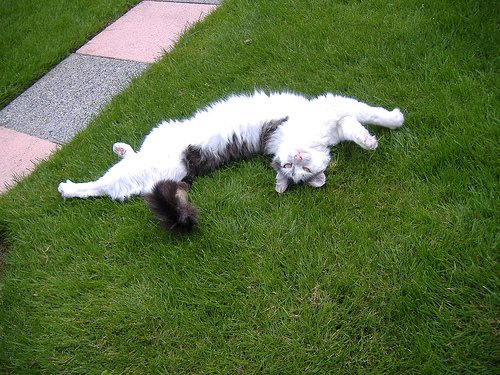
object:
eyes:
[284, 162, 293, 169]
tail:
[152, 176, 204, 241]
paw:
[384, 98, 405, 132]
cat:
[56, 87, 404, 234]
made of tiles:
[0, 0, 235, 192]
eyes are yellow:
[303, 165, 313, 175]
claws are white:
[359, 137, 378, 149]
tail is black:
[141, 181, 215, 239]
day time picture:
[0, 0, 500, 372]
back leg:
[82, 169, 126, 193]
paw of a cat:
[106, 131, 136, 154]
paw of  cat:
[359, 130, 384, 164]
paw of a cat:
[55, 170, 88, 205]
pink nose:
[291, 151, 310, 165]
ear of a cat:
[274, 172, 289, 193]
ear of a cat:
[310, 173, 326, 188]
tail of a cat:
[139, 175, 215, 242]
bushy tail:
[149, 179, 201, 235]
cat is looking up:
[269, 146, 326, 194]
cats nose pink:
[292, 154, 305, 163]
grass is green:
[0, 0, 500, 375]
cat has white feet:
[58, 178, 77, 196]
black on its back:
[179, 116, 294, 188]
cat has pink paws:
[389, 108, 404, 130]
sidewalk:
[42, 55, 132, 122]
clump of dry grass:
[300, 285, 329, 311]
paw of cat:
[358, 124, 386, 163]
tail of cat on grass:
[139, 176, 202, 238]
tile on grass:
[79, 0, 211, 60]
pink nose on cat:
[290, 153, 311, 163]